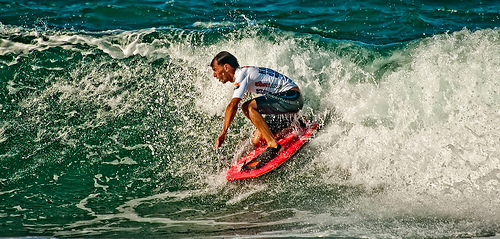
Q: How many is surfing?
A: One man.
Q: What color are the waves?
A: White.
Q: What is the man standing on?
A: Surfing board.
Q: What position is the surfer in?
A: Crouched down.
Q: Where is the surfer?
A: In the ocean.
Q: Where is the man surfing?
A: On an ocean wave.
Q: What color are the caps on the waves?
A: White.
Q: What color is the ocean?
A: Greenish blue.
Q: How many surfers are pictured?
A: One.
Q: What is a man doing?
A: Surfing.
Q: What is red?
A: Surfboard.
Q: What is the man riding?
A: A wave.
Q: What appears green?
A: The water.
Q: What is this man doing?
A: Surfboarding.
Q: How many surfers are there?
A: 1.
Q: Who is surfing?
A: A man.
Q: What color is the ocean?
A: Bluish green.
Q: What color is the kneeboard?
A: Red.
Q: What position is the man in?
A: Kneeling.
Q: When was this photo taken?
A: During the day.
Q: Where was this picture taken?
A: At the beach.